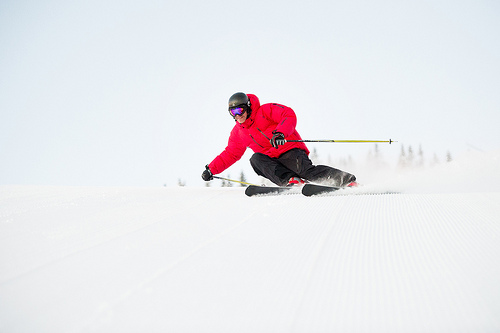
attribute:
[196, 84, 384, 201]
man — has black helmet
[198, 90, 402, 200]
coat — red and black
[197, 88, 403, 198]
man — has blue goggles, has black pants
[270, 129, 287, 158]
gloves — black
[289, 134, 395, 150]
poles — black, yellow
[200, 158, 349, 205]
skis — red, black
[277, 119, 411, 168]
ski poles — black, yellow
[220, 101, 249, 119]
googles — black, frame, protective 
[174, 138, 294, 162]
gloves — winter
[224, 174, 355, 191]
skis — black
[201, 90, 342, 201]
gear — ski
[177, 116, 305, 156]
jacket — red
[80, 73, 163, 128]
sky — blue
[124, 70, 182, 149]
clouds — white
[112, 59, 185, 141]
clouds — white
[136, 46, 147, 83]
sky — blue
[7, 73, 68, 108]
sky — blue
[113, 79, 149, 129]
clouds — white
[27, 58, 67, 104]
clouds — white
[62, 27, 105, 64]
sky — blue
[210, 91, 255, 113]
helmet — black, safety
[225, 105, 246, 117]
googles — ski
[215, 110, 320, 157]
jacket — red, winter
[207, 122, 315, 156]
jacket — long, sleeve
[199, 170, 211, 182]
glove — black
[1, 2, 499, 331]
snow — white